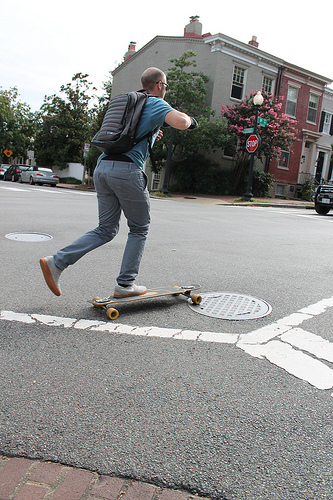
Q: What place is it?
A: It is a street.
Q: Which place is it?
A: It is a street.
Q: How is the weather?
A: It is overcast.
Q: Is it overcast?
A: Yes, it is overcast.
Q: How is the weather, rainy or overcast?
A: It is overcast.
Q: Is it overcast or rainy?
A: It is overcast.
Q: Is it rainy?
A: No, it is overcast.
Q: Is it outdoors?
A: Yes, it is outdoors.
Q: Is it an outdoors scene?
A: Yes, it is outdoors.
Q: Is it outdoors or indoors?
A: It is outdoors.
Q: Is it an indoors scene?
A: No, it is outdoors.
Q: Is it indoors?
A: No, it is outdoors.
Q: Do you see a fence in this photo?
A: No, there are no fences.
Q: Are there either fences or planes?
A: No, there are no fences or planes.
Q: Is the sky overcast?
A: Yes, the sky is overcast.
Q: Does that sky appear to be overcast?
A: Yes, the sky is overcast.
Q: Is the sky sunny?
A: No, the sky is overcast.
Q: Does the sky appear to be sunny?
A: No, the sky is overcast.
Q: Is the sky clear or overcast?
A: The sky is overcast.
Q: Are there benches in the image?
A: No, there are no benches.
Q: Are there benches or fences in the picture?
A: No, there are no benches or fences.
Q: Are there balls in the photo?
A: No, there are no balls.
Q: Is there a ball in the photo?
A: No, there are no balls.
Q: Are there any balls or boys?
A: No, there are no balls or boys.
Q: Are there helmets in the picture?
A: No, there are no helmets.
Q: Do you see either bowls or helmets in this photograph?
A: No, there are no helmets or bowls.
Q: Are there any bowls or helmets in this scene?
A: No, there are no helmets or bowls.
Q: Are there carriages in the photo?
A: No, there are no carriages.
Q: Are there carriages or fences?
A: No, there are no carriages or fences.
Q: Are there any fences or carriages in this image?
A: No, there are no carriages or fences.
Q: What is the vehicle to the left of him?
A: The vehicle is a car.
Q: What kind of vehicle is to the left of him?
A: The vehicle is a car.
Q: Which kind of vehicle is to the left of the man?
A: The vehicle is a car.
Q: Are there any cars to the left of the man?
A: Yes, there is a car to the left of the man.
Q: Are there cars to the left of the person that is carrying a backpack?
A: Yes, there is a car to the left of the man.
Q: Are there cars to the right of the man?
A: No, the car is to the left of the man.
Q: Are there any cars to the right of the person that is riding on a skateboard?
A: No, the car is to the left of the man.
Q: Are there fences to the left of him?
A: No, there is a car to the left of the man.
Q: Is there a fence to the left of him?
A: No, there is a car to the left of the man.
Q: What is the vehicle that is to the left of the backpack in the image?
A: The vehicle is a car.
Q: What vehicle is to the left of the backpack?
A: The vehicle is a car.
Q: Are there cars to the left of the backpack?
A: Yes, there is a car to the left of the backpack.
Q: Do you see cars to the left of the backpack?
A: Yes, there is a car to the left of the backpack.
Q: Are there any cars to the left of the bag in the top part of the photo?
A: Yes, there is a car to the left of the backpack.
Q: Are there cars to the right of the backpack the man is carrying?
A: No, the car is to the left of the backpack.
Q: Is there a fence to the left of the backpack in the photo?
A: No, there is a car to the left of the backpack.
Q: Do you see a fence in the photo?
A: No, there are no fences.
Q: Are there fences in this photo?
A: No, there are no fences.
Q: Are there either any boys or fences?
A: No, there are no fences or boys.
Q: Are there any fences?
A: No, there are no fences.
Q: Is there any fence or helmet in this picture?
A: No, there are no fences or helmets.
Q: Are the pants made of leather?
A: No, the pants are made of denim.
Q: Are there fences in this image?
A: No, there are no fences.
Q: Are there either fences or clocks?
A: No, there are no fences or clocks.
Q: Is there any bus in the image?
A: No, there are no buses.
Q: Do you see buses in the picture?
A: No, there are no buses.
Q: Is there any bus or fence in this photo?
A: No, there are no buses or fences.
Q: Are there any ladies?
A: No, there are no ladies.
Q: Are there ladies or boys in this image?
A: No, there are no ladies or boys.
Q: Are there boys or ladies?
A: No, there are no ladies or boys.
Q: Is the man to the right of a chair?
A: No, the man is to the right of the car.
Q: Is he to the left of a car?
A: No, the man is to the right of a car.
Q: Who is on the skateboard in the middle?
A: The man is on the skateboard.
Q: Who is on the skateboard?
A: The man is on the skateboard.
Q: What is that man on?
A: The man is on the skateboard.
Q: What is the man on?
A: The man is on the skateboard.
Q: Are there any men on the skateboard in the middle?
A: Yes, there is a man on the skateboard.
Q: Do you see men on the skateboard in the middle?
A: Yes, there is a man on the skateboard.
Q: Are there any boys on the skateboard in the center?
A: No, there is a man on the skateboard.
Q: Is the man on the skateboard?
A: Yes, the man is on the skateboard.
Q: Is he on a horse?
A: No, the man is on the skateboard.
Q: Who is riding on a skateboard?
A: The man is riding on a skateboard.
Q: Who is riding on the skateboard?
A: The man is riding on a skateboard.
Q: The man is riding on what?
A: The man is riding on a skateboard.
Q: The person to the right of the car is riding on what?
A: The man is riding on a skateboard.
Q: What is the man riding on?
A: The man is riding on a skateboard.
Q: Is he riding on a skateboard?
A: Yes, the man is riding on a skateboard.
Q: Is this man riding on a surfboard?
A: No, the man is riding on a skateboard.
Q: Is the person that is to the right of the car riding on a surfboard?
A: No, the man is riding on a skateboard.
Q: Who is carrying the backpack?
A: The man is carrying the backpack.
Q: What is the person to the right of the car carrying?
A: The man is carrying a backpack.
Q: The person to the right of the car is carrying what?
A: The man is carrying a backpack.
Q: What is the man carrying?
A: The man is carrying a backpack.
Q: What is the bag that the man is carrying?
A: The bag is a backpack.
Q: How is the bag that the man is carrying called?
A: The bag is a backpack.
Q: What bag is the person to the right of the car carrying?
A: The man is carrying a backpack.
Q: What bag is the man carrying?
A: The man is carrying a backpack.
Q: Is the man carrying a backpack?
A: Yes, the man is carrying a backpack.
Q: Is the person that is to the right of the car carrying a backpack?
A: Yes, the man is carrying a backpack.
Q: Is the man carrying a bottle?
A: No, the man is carrying a backpack.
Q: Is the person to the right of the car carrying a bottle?
A: No, the man is carrying a backpack.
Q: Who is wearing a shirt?
A: The man is wearing a shirt.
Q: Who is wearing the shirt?
A: The man is wearing a shirt.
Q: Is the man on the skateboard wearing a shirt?
A: Yes, the man is wearing a shirt.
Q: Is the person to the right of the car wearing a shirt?
A: Yes, the man is wearing a shirt.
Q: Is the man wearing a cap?
A: No, the man is wearing a shirt.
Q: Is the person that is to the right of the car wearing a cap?
A: No, the man is wearing a shirt.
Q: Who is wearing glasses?
A: The man is wearing glasses.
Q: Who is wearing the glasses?
A: The man is wearing glasses.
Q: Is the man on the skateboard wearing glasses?
A: Yes, the man is wearing glasses.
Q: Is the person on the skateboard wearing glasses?
A: Yes, the man is wearing glasses.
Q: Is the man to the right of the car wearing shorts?
A: No, the man is wearing glasses.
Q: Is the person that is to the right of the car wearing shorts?
A: No, the man is wearing glasses.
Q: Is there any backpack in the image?
A: Yes, there is a backpack.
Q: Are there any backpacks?
A: Yes, there is a backpack.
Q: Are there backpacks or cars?
A: Yes, there is a backpack.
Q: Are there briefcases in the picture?
A: No, there are no briefcases.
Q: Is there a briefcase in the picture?
A: No, there are no briefcases.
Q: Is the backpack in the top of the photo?
A: Yes, the backpack is in the top of the image.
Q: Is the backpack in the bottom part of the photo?
A: No, the backpack is in the top of the image.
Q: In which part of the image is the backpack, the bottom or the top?
A: The backpack is in the top of the image.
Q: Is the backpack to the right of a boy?
A: No, the backpack is to the right of the car.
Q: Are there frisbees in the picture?
A: No, there are no frisbees.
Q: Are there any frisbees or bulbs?
A: No, there are no frisbees or bulbs.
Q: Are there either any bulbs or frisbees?
A: No, there are no frisbees or bulbs.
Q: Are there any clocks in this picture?
A: No, there are no clocks.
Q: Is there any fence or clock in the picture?
A: No, there are no clocks or fences.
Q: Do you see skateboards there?
A: Yes, there is a skateboard.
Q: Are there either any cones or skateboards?
A: Yes, there is a skateboard.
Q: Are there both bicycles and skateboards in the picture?
A: No, there is a skateboard but no bicycles.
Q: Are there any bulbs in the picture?
A: No, there are no bulbs.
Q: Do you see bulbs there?
A: No, there are no bulbs.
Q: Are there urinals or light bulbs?
A: No, there are no light bulbs or urinals.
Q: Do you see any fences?
A: No, there are no fences.